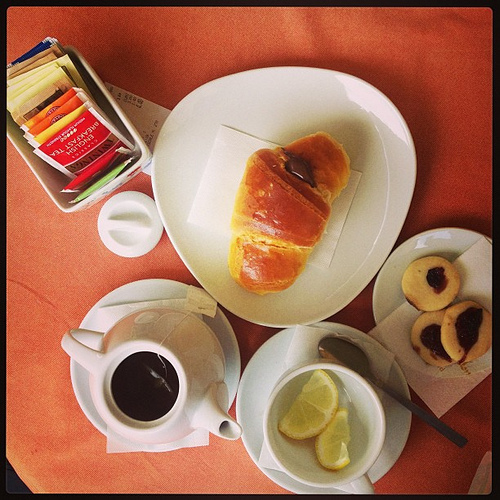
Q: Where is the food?
A: On plates.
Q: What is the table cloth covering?
A: A table.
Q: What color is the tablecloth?
A: Peach.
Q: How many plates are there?
A: 4.